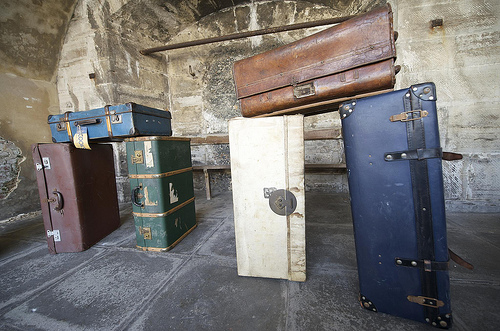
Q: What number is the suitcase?
A: Three.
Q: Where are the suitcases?
A: In a room.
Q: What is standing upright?
A: Red suitcase.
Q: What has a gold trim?
A: Green suitcase.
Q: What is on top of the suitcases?
A: Brown leather suitcase.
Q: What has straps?
A: Blue suitcase.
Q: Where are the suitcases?
A: On floor.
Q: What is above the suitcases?
A: Metal bar.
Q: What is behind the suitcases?
A: Wooden bench.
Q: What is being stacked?
A: Suitcases.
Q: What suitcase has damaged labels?
A: Green one.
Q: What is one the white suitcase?
A: Circular latch.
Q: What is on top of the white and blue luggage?
A: Brown suitcase.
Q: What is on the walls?
A: Mildew.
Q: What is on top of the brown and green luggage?
A: Blue suitcase.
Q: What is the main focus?
A: Luggage.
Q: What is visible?
A: Suitcase.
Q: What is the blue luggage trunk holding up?
A: The brown case.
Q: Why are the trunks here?
A: The trunks are being stored.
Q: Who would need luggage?
A: Travellers need luggage.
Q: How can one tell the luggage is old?
A: They appear to be worn.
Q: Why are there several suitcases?
A: There may be several travellers.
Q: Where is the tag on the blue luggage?
A: The handle.